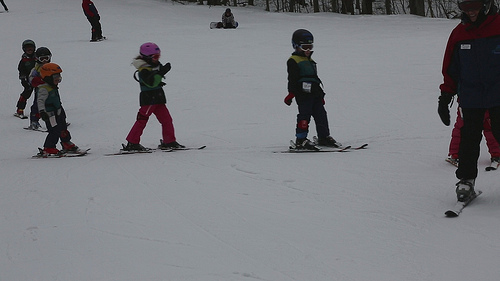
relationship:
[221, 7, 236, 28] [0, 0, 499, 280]
person sitting snow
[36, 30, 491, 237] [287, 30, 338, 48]
kids wearing googles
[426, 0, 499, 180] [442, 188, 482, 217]
adult wearing skis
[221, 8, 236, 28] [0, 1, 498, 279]
person on ground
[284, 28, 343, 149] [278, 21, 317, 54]
kids wearing a helmet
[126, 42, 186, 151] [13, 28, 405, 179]
kid skiing on snow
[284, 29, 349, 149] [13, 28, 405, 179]
kids skiing on snow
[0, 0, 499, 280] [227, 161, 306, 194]
snow has tracks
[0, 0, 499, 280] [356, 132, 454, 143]
snow has tracks